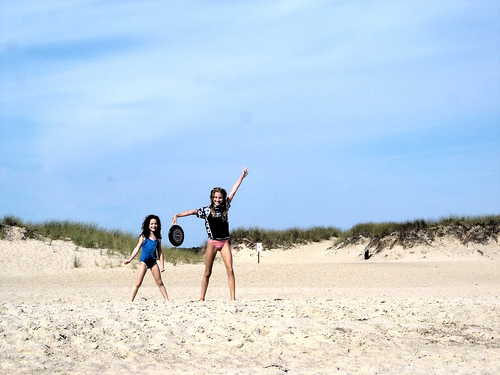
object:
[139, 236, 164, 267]
blue swimsuit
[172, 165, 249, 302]
girl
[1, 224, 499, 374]
beach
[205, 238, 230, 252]
bottom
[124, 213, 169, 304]
girl